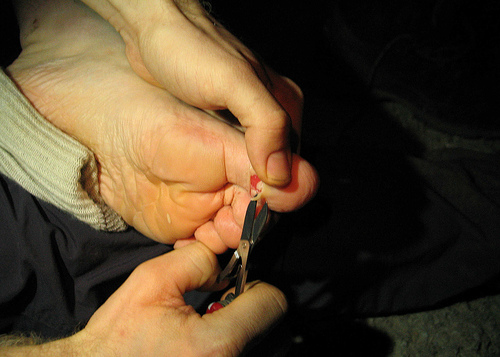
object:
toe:
[230, 187, 260, 226]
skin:
[250, 190, 263, 202]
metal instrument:
[197, 199, 270, 316]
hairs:
[1, 321, 94, 355]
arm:
[1, 329, 143, 357]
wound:
[247, 178, 265, 191]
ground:
[338, 130, 362, 165]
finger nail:
[265, 150, 287, 182]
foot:
[8, 42, 318, 247]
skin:
[151, 119, 207, 179]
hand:
[73, 238, 287, 357]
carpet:
[370, 295, 500, 357]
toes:
[193, 224, 224, 252]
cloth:
[0, 67, 126, 232]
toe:
[212, 205, 243, 249]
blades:
[241, 197, 253, 238]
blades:
[257, 205, 275, 238]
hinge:
[237, 239, 249, 257]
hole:
[249, 174, 264, 189]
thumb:
[228, 76, 293, 186]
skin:
[248, 171, 263, 200]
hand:
[121, 10, 305, 186]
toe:
[232, 144, 318, 211]